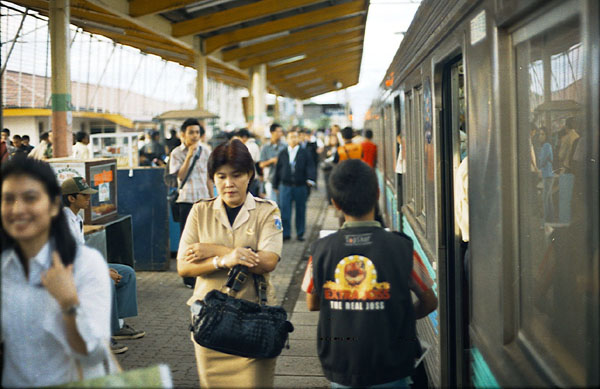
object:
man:
[53, 177, 147, 354]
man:
[167, 117, 215, 288]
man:
[272, 132, 317, 243]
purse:
[186, 263, 293, 359]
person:
[302, 158, 439, 389]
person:
[175, 139, 283, 389]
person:
[0, 157, 113, 389]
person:
[258, 122, 288, 207]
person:
[333, 127, 363, 164]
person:
[139, 131, 166, 164]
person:
[325, 124, 343, 163]